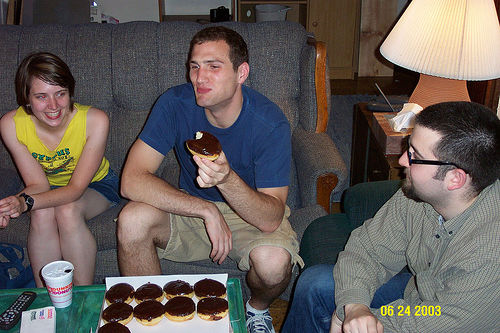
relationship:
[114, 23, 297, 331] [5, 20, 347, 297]
man on sofa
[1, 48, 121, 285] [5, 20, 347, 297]
woman on sofa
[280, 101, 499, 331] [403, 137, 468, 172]
man wearing eyeglasses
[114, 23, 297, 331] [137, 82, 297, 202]
man wearing shirt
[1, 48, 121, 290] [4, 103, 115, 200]
woman wearing shirt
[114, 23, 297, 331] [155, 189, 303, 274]
man wearing khaki shorts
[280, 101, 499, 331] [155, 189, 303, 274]
man wearing khaki shorts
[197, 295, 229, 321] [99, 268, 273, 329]
chocolate donut in box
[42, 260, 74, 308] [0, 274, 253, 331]
cup on table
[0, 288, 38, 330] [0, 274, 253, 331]
remote control on table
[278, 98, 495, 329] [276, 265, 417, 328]
seated man wearing blue jeans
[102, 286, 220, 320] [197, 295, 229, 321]
chocolate on chocolate donut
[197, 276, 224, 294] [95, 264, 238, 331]
chocolate donut in box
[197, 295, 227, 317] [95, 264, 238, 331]
chocolate donut in box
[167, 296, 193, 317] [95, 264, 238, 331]
chocolate donut in box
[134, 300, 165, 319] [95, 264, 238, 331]
chocolate donut in box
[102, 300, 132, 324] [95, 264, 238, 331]
chocolate donut in box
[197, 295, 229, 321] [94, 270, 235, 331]
chocolate donut in box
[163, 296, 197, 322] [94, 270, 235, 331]
chocolate donut in box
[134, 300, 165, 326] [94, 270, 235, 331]
chocolate donut in box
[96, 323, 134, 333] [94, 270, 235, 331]
donut in box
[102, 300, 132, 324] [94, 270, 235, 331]
chocolate donut in box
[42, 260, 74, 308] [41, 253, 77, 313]
cup from dunkin donuts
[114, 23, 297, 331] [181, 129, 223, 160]
man eat donut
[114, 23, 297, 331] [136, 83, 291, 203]
man wears t-shirt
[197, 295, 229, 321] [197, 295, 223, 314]
chocolate donut has frosting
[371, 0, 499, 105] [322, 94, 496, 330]
lamp behind man